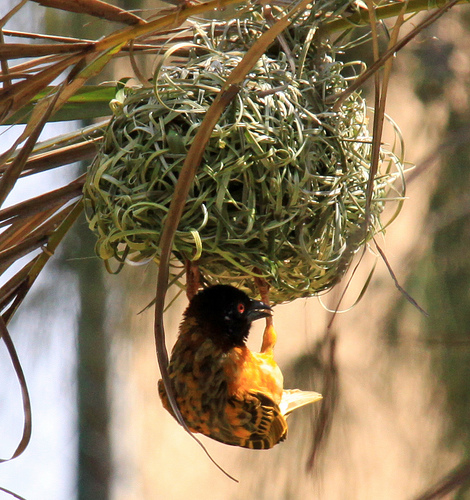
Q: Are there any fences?
A: No, there are no fences.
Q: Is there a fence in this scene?
A: No, there are no fences.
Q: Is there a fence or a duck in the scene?
A: No, there are no fences or ducks.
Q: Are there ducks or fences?
A: No, there are no fences or ducks.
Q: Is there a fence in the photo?
A: No, there are no fences.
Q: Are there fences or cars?
A: No, there are no fences or cars.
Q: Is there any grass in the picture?
A: Yes, there is grass.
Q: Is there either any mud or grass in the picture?
A: Yes, there is grass.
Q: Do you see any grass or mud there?
A: Yes, there is grass.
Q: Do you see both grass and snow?
A: No, there is grass but no snow.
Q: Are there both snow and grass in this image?
A: No, there is grass but no snow.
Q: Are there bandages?
A: No, there are no bandages.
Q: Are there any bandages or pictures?
A: No, there are no bandages or pictures.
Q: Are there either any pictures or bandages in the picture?
A: No, there are no bandages or pictures.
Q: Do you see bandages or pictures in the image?
A: No, there are no bandages or pictures.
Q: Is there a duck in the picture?
A: No, there are no ducks.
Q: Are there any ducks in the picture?
A: No, there are no ducks.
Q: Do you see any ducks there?
A: No, there are no ducks.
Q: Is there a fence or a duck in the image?
A: No, there are no ducks or fences.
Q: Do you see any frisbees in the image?
A: No, there are no frisbees.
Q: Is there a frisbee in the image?
A: No, there are no frisbees.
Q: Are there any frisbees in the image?
A: No, there are no frisbees.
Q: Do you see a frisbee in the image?
A: No, there are no frisbees.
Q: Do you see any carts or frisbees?
A: No, there are no frisbees or carts.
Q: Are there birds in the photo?
A: Yes, there is a bird.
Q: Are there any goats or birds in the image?
A: Yes, there is a bird.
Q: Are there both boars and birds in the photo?
A: No, there is a bird but no boars.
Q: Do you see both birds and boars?
A: No, there is a bird but no boars.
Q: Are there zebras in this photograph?
A: No, there are no zebras.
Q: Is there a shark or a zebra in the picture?
A: No, there are no zebras or sharks.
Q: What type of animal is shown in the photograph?
A: The animal is a bird.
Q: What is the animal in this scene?
A: The animal is a bird.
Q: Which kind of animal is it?
A: The animal is a bird.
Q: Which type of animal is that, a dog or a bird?
A: That is a bird.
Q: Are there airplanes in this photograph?
A: No, there are no airplanes.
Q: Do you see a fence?
A: No, there are no fences.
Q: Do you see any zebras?
A: No, there are no zebras.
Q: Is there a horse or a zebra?
A: No, there are no zebras or horses.